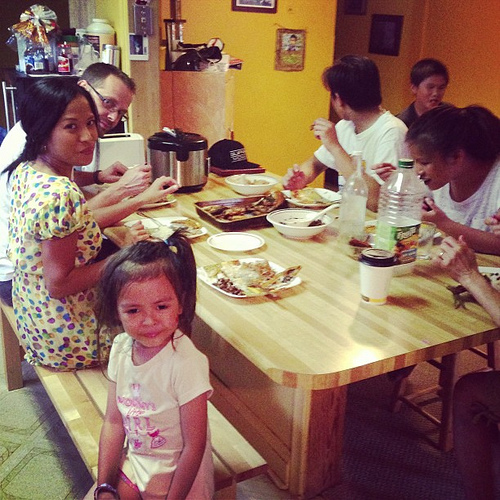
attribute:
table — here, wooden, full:
[100, 172, 500, 390]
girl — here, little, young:
[93, 229, 214, 500]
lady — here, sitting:
[1, 74, 182, 372]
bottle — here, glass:
[339, 151, 368, 239]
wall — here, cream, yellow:
[159, 0, 499, 187]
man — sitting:
[2, 62, 152, 307]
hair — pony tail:
[93, 228, 198, 383]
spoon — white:
[290, 202, 341, 226]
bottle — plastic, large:
[378, 157, 423, 278]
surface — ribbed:
[381, 185, 426, 225]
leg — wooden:
[2, 309, 24, 392]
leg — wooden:
[391, 375, 405, 415]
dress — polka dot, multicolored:
[6, 162, 113, 372]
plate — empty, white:
[207, 232, 266, 251]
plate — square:
[198, 259, 304, 299]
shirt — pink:
[105, 329, 215, 499]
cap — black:
[211, 139, 261, 170]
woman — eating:
[401, 104, 499, 256]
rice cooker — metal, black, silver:
[146, 126, 208, 193]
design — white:
[228, 146, 248, 165]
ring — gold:
[438, 250, 447, 259]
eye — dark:
[157, 304, 169, 310]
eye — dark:
[128, 308, 141, 313]